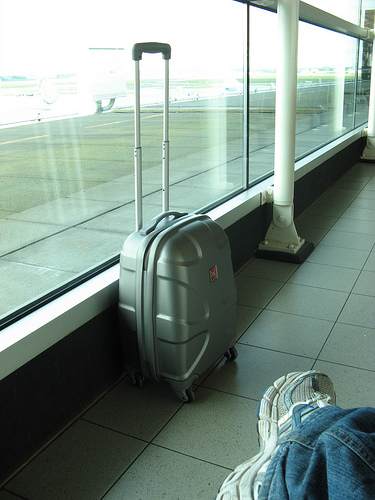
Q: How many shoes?
A: One.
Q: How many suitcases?
A: One.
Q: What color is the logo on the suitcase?
A: Red.